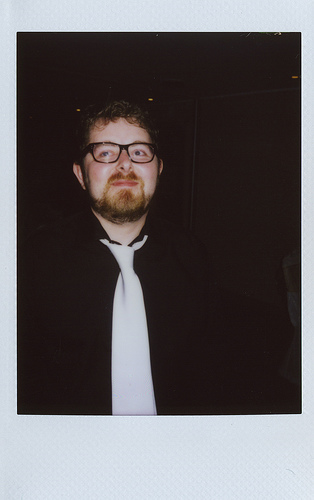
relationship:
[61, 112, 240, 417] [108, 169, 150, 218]
man with beard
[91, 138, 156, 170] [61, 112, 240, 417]
glasses on man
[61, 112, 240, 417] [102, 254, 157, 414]
man wearing tie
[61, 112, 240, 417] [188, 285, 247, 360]
man in shirt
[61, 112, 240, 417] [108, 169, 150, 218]
man has beard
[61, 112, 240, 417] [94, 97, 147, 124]
man has hair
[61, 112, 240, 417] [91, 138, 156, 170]
man with glasses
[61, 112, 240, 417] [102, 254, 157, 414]
man with tie